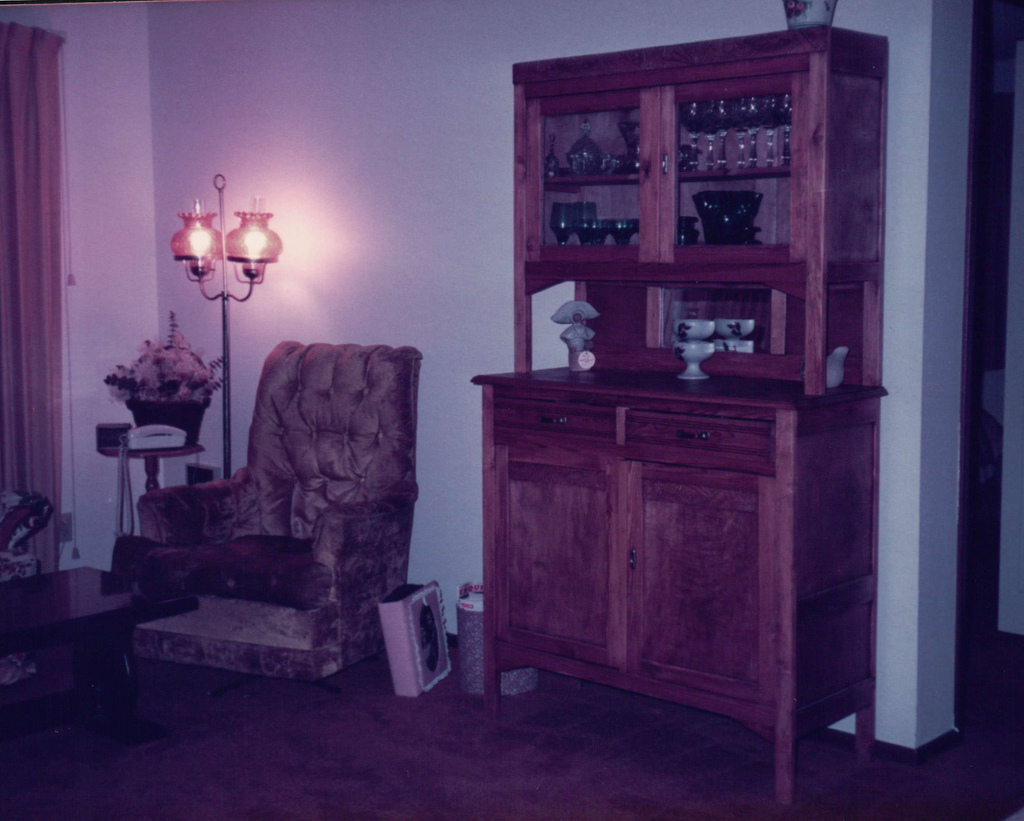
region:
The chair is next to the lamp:
[111, 141, 492, 720]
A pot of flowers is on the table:
[59, 281, 325, 689]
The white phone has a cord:
[29, 228, 308, 734]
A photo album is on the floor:
[358, 445, 505, 765]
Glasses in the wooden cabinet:
[617, 66, 911, 488]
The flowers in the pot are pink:
[96, 306, 236, 478]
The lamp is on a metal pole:
[175, 200, 346, 552]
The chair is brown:
[133, 279, 503, 716]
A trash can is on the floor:
[419, 512, 572, 778]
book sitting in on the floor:
[367, 542, 453, 738]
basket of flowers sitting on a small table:
[87, 327, 227, 568]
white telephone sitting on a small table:
[80, 312, 233, 544]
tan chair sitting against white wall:
[124, 298, 416, 714]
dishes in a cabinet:
[479, 49, 892, 305]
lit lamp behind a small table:
[90, 150, 340, 487]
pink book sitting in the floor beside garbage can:
[340, 576, 540, 745]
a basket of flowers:
[114, 327, 222, 442]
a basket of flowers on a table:
[101, 324, 209, 467]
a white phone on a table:
[115, 425, 201, 465]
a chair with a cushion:
[144, 316, 416, 672]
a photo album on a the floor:
[367, 566, 462, 712]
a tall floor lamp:
[162, 150, 274, 486]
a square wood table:
[22, 561, 191, 743]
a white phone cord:
[95, 430, 141, 532]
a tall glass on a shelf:
[731, 85, 760, 174]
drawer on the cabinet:
[639, 407, 757, 471]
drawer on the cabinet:
[504, 408, 603, 462]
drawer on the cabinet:
[582, 287, 660, 346]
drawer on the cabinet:
[637, 94, 774, 156]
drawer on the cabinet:
[551, 217, 653, 266]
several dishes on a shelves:
[553, 112, 788, 261]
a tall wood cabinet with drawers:
[488, 33, 878, 798]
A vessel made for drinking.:
[770, 92, 806, 181]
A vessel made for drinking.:
[739, 95, 765, 165]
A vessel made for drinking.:
[754, 83, 786, 164]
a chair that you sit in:
[108, 323, 418, 679]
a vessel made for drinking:
[552, 194, 572, 248]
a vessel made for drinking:
[560, 193, 602, 229]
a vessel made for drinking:
[705, 89, 722, 167]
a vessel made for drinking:
[754, 96, 777, 167]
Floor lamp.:
[164, 168, 289, 498]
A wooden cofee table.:
[9, 551, 222, 741]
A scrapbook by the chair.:
[370, 570, 472, 706]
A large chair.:
[117, 319, 430, 687]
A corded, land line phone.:
[116, 414, 214, 571]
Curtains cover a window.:
[6, 18, 70, 576]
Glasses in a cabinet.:
[679, 98, 801, 171]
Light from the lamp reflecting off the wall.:
[278, 202, 362, 283]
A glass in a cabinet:
[546, 199, 573, 247]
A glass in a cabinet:
[573, 199, 594, 222]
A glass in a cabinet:
[614, 217, 637, 247]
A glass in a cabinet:
[591, 218, 608, 241]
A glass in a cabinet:
[692, 192, 721, 240]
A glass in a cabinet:
[566, 110, 598, 169]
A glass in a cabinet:
[543, 135, 560, 171]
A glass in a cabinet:
[616, 117, 633, 175]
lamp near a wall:
[168, 153, 280, 318]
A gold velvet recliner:
[131, 324, 411, 691]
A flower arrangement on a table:
[103, 329, 221, 443]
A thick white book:
[371, 582, 467, 700]